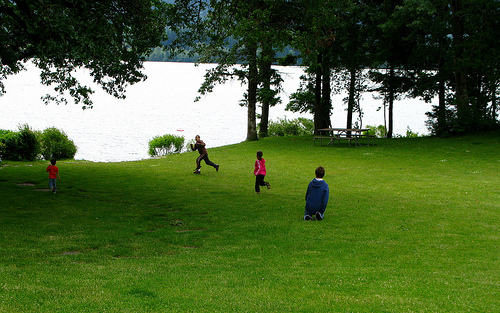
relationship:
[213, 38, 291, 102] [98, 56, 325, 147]
tree by lake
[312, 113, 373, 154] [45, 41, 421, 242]
table in park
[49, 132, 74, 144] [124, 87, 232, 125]
plants near water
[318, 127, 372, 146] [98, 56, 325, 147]
table near lake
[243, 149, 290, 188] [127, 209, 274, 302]
child on grass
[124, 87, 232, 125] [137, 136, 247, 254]
water seen behind grass